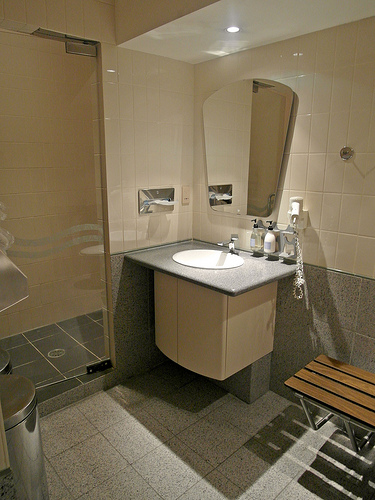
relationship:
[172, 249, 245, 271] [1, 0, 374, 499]
sink in bathroom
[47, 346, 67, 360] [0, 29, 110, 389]
drain in shower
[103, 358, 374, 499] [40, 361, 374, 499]
shadows on ground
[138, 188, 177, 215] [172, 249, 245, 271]
paper tower dispense next to sink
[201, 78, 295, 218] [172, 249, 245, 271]
mirror above sink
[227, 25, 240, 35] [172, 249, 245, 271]
light above sink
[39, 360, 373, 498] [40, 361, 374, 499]
tile on ground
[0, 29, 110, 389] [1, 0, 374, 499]
shower in bathroom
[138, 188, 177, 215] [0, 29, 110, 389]
paper tower dispense near shower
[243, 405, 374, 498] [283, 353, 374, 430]
shadow from bench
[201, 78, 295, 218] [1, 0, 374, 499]
mirror in bathroom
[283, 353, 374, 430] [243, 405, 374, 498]
bench making a shadow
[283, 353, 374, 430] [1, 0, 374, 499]
bench in bathroom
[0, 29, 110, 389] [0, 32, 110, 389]
shower has a glass door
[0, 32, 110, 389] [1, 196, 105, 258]
shower door has etching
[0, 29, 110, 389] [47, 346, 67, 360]
shower has a drain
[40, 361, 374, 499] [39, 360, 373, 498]
ground has tile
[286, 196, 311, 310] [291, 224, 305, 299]
hairdryer has a cord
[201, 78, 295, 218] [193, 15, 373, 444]
mirror on wall